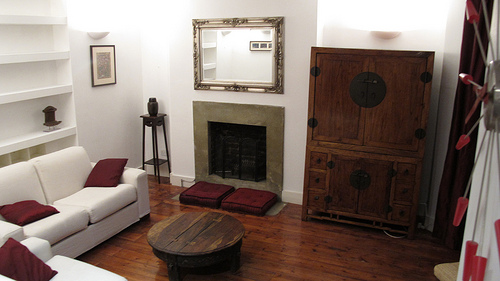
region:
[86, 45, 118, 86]
Framed picture on the wall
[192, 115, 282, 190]
Fireplace underneath the mirror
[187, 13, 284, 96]
Rectangular mirror above the fire place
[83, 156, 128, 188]
Dark red pillow on the edge of the couch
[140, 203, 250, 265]
Circular dark wooden table in the center of the room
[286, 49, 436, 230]
Dark wooden cabinet against the wall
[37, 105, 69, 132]
Item on the white shelves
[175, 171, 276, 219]
Two red pillows in front of the fire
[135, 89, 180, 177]
Dark wooden table with vase in the corner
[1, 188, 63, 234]
Dark red pillow on couch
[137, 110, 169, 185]
table on the corner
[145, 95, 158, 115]
black vase on table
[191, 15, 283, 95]
mirror hanging on wall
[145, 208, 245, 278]
coffee table in front of sofa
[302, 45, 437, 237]
entertainment set in the livingroom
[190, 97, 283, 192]
fireplace under mirror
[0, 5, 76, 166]
shelf behind the couch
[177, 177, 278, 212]
two cushions in front of fireplace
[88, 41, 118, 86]
painting on wall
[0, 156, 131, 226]
two cushions on the sofa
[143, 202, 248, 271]
A round wooden coffee table.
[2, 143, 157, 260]
A white sofa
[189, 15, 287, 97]
A large mirror.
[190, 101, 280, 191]
A fireplace.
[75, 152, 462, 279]
Dark brown hardwood floors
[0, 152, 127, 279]
Square burgundy accent pillows on the sofas.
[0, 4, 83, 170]
A white built in the wall shelf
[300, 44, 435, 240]
A brown wooden closet.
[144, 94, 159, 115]
A black vase.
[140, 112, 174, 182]
A small dark stand.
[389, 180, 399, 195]
part of a drawer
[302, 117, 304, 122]
part of a wall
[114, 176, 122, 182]
part of a pillow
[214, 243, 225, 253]
part of a table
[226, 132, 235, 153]
part of a fire place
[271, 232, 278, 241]
part of the floor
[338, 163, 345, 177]
part of a drawer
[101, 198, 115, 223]
edge of a seat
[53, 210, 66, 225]
part of a sofa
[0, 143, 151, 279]
a white couch in the living room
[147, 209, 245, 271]
a small, wooden coffee table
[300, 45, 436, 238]
a large, wooden chest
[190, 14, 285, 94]
a large mirror on the wall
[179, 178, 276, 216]
red cushions in front of the fireplace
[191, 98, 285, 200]
a fireplace in the living room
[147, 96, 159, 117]
a small black vase on a stand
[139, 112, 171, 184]
a tall black stand in the corner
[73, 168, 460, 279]
hardwood floor in the living room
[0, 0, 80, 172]
white shelves in the living room